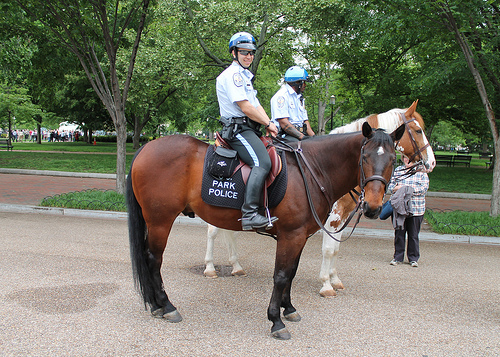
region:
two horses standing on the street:
[115, 22, 465, 287]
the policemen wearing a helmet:
[207, 25, 267, 85]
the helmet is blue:
[213, 10, 268, 75]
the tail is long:
[96, 136, 176, 313]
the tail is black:
[100, 115, 183, 307]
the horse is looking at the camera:
[328, 114, 430, 263]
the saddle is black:
[187, 137, 249, 212]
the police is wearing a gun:
[195, 92, 282, 159]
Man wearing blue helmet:
[218, 32, 278, 234]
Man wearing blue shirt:
[215, 31, 287, 233]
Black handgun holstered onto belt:
[215, 114, 236, 141]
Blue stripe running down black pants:
[237, 133, 261, 167]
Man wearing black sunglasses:
[213, 30, 280, 230]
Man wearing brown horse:
[213, 30, 280, 233]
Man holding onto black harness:
[215, 29, 287, 231]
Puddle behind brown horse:
[3, 278, 121, 311]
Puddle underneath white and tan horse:
[187, 256, 242, 279]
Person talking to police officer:
[377, 148, 435, 269]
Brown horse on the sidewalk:
[100, 119, 402, 346]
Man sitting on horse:
[212, 25, 289, 232]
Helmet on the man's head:
[223, 32, 255, 52]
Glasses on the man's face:
[235, 44, 257, 59]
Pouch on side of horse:
[200, 141, 244, 188]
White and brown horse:
[200, 101, 439, 298]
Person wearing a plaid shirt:
[385, 144, 433, 272]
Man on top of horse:
[263, 57, 315, 140]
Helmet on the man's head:
[277, 60, 309, 82]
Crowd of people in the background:
[3, 115, 93, 151]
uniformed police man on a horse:
[183, 18, 305, 253]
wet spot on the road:
[10, 275, 124, 318]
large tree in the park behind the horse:
[27, 9, 155, 204]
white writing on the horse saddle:
[206, 176, 241, 200]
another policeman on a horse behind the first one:
[263, 62, 325, 137]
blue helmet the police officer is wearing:
[228, 30, 258, 47]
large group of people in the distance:
[11, 123, 77, 141]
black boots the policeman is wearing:
[242, 200, 279, 237]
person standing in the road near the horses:
[387, 148, 433, 272]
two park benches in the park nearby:
[433, 149, 478, 171]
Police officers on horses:
[123, 31, 438, 341]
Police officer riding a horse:
[121, 29, 406, 340]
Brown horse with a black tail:
[123, 120, 407, 339]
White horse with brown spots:
[202, 96, 435, 298]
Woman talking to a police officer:
[378, 147, 430, 269]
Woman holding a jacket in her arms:
[378, 149, 430, 269]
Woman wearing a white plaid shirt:
[376, 147, 430, 269]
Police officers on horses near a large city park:
[0, 0, 499, 356]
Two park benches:
[428, 152, 475, 169]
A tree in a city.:
[24, 0, 161, 202]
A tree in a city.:
[346, 36, 436, 161]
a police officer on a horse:
[209, 24, 285, 232]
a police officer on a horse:
[271, 59, 328, 135]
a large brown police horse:
[114, 114, 438, 326]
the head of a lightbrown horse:
[391, 103, 441, 175]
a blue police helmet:
[227, 18, 259, 61]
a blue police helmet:
[284, 61, 314, 86]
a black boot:
[235, 208, 281, 237]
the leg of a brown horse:
[268, 230, 299, 344]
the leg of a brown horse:
[321, 225, 341, 296]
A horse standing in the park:
[125, 121, 411, 337]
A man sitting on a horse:
[216, 30, 281, 231]